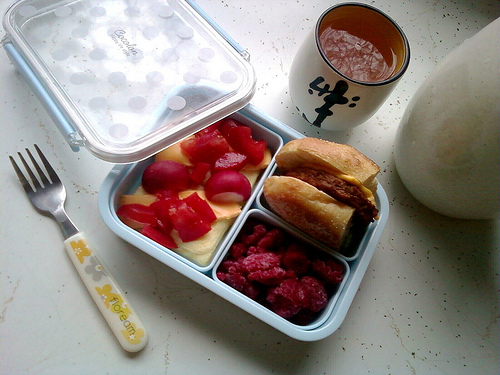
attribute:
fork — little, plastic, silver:
[8, 142, 148, 356]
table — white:
[3, 3, 496, 370]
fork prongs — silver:
[6, 142, 74, 240]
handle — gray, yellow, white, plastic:
[63, 232, 153, 358]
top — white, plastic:
[2, 0, 255, 166]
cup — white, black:
[288, 3, 412, 133]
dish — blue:
[91, 74, 390, 357]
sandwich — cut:
[260, 136, 382, 251]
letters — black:
[104, 24, 138, 60]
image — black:
[296, 71, 358, 132]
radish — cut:
[202, 167, 250, 206]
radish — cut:
[142, 160, 190, 195]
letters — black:
[111, 296, 138, 339]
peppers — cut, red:
[117, 116, 266, 251]